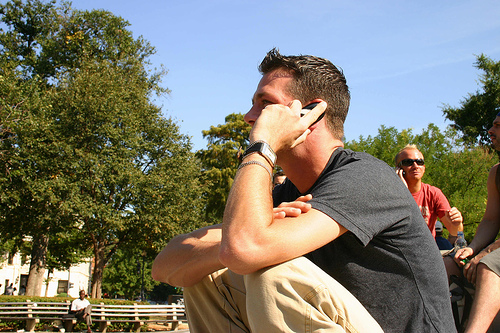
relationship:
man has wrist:
[180, 55, 453, 332] [234, 132, 283, 189]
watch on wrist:
[237, 142, 279, 170] [234, 132, 283, 189]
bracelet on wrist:
[236, 162, 274, 181] [234, 132, 283, 189]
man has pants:
[180, 55, 453, 332] [183, 255, 384, 332]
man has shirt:
[180, 55, 453, 332] [274, 148, 456, 332]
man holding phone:
[180, 55, 453, 332] [301, 100, 325, 128]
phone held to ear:
[301, 100, 325, 128] [302, 98, 322, 130]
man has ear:
[180, 55, 453, 332] [302, 98, 322, 130]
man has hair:
[180, 55, 453, 332] [257, 45, 350, 139]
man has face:
[392, 143, 464, 237] [402, 149, 426, 178]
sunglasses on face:
[396, 158, 425, 166] [402, 149, 426, 178]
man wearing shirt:
[392, 143, 464, 237] [410, 180, 451, 238]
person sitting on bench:
[71, 289, 94, 332] [1, 300, 189, 332]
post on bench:
[172, 302, 178, 321] [1, 300, 189, 332]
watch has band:
[237, 142, 279, 170] [241, 141, 263, 158]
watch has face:
[237, 142, 279, 170] [261, 142, 278, 167]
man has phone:
[180, 55, 453, 332] [301, 100, 325, 128]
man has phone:
[392, 143, 464, 237] [396, 166, 406, 176]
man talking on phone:
[180, 55, 453, 332] [301, 100, 325, 128]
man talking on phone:
[392, 143, 464, 237] [396, 166, 406, 176]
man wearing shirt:
[180, 55, 453, 332] [274, 148, 456, 332]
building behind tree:
[0, 221, 94, 298] [1, 2, 184, 299]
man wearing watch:
[180, 55, 453, 332] [237, 142, 279, 170]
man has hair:
[392, 143, 464, 237] [395, 142, 418, 166]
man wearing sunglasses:
[392, 143, 464, 237] [396, 158, 425, 166]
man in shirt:
[392, 143, 464, 237] [410, 180, 451, 238]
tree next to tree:
[1, 2, 184, 299] [84, 113, 202, 298]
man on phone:
[180, 55, 453, 332] [301, 100, 325, 128]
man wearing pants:
[180, 55, 453, 332] [183, 255, 384, 332]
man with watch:
[180, 55, 453, 332] [237, 142, 279, 170]